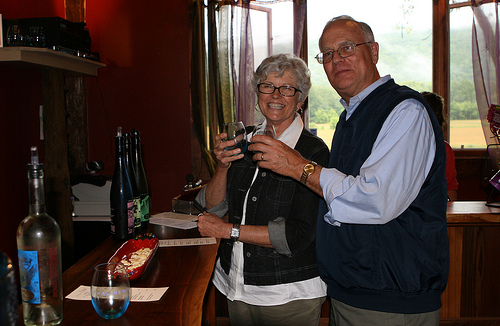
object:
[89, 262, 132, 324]
glass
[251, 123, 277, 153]
glass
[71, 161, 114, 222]
cash register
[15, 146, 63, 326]
bottle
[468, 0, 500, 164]
drapery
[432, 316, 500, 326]
ground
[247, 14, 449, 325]
man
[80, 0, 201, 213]
walls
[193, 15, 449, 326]
couple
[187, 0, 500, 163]
window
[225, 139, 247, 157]
wine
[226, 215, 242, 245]
watch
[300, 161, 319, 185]
watch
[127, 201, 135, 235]
labels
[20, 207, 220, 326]
bar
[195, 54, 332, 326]
woman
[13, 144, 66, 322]
wine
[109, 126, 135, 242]
wine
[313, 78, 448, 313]
jacket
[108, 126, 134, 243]
bottle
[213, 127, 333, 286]
sweater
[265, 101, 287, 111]
mouth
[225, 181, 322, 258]
arm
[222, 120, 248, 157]
glass